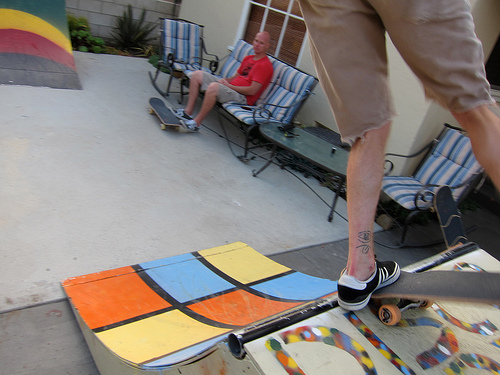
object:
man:
[167, 21, 277, 133]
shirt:
[224, 53, 275, 112]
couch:
[181, 36, 318, 179]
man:
[295, 0, 498, 313]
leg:
[305, 14, 406, 309]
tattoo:
[355, 225, 375, 258]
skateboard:
[422, 182, 475, 249]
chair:
[381, 116, 495, 251]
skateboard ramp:
[1, 1, 86, 94]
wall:
[66, 0, 180, 61]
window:
[242, 0, 308, 67]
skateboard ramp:
[52, 238, 337, 369]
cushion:
[381, 126, 483, 211]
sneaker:
[332, 256, 401, 309]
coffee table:
[252, 118, 396, 222]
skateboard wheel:
[371, 303, 406, 327]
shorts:
[295, 0, 499, 148]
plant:
[107, 4, 158, 57]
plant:
[66, 12, 110, 58]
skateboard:
[146, 95, 186, 138]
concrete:
[0, 45, 386, 312]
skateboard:
[371, 260, 499, 323]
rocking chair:
[144, 15, 221, 98]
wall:
[175, 0, 499, 196]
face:
[252, 35, 270, 52]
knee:
[204, 82, 223, 102]